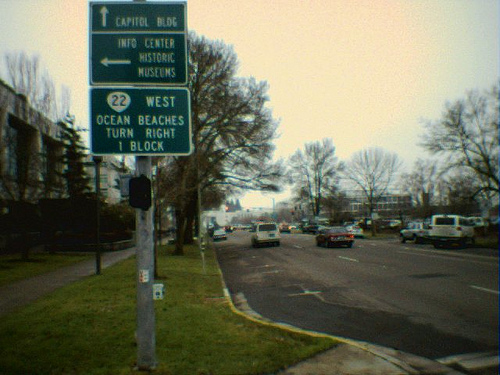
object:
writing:
[98, 15, 180, 151]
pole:
[135, 154, 158, 371]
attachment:
[152, 284, 163, 301]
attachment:
[139, 270, 150, 283]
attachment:
[129, 174, 152, 210]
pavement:
[221, 239, 498, 367]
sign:
[89, 2, 188, 33]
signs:
[85, 85, 193, 152]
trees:
[333, 148, 403, 216]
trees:
[399, 160, 450, 218]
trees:
[422, 86, 499, 218]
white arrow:
[101, 57, 132, 67]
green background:
[91, 33, 185, 82]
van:
[427, 213, 477, 249]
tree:
[52, 116, 98, 247]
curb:
[247, 314, 280, 331]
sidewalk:
[2, 256, 82, 304]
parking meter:
[199, 235, 207, 270]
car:
[315, 229, 354, 248]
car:
[251, 222, 281, 247]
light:
[225, 206, 230, 212]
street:
[205, 226, 497, 370]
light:
[350, 235, 354, 237]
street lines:
[337, 256, 361, 264]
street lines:
[465, 281, 497, 299]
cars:
[213, 230, 228, 242]